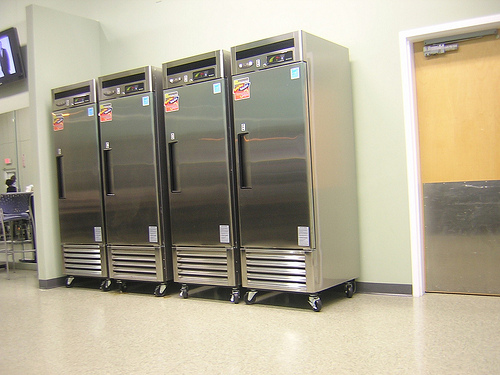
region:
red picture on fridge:
[228, 68, 255, 103]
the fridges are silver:
[38, 45, 360, 310]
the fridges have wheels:
[52, 258, 387, 324]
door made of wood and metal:
[401, 26, 498, 303]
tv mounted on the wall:
[0, 23, 45, 85]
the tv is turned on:
[0, 28, 23, 88]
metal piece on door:
[415, 41, 483, 61]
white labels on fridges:
[83, 213, 335, 257]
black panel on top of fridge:
[226, 36, 307, 61]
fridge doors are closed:
[43, 56, 323, 315]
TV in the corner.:
[0, 15, 31, 92]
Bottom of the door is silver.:
[416, 178, 498, 296]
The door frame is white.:
[401, 24, 498, 299]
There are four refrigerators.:
[47, 20, 350, 304]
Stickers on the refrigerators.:
[47, 74, 267, 129]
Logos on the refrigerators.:
[276, 62, 309, 95]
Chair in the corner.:
[1, 186, 40, 264]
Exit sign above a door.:
[1, 153, 18, 178]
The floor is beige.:
[14, 292, 492, 374]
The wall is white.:
[36, 17, 408, 70]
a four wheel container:
[220, 20, 379, 316]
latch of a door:
[416, 33, 497, 54]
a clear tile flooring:
[110, 312, 262, 367]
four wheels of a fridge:
[246, 278, 363, 307]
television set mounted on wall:
[0, 21, 27, 87]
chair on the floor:
[0, 193, 43, 278]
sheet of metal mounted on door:
[421, 174, 499, 297]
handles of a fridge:
[233, 127, 260, 189]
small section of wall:
[22, 8, 118, 290]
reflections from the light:
[277, 323, 307, 370]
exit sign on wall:
[3, 157, 13, 167]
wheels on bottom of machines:
[63, 272, 358, 314]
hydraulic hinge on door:
[422, 40, 498, 60]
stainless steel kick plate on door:
[420, 179, 497, 296]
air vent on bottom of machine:
[62, 242, 104, 274]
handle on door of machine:
[234, 130, 252, 191]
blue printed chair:
[0, 190, 39, 270]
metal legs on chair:
[1, 220, 40, 269]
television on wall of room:
[0, 24, 25, 87]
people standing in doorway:
[4, 170, 16, 192]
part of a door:
[478, 225, 480, 232]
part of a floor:
[411, 316, 413, 319]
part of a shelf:
[331, 240, 342, 262]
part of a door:
[260, 244, 264, 256]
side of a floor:
[221, 291, 225, 306]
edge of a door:
[400, 196, 415, 227]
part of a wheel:
[317, 305, 332, 320]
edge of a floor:
[203, 311, 205, 314]